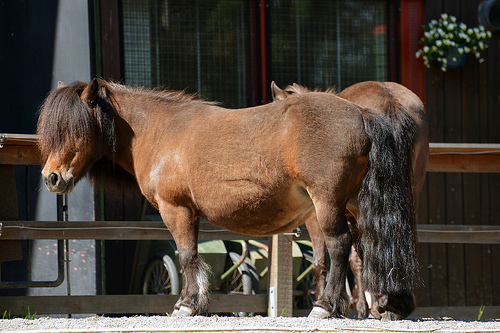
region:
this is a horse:
[22, 44, 448, 274]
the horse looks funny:
[29, 54, 487, 268]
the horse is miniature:
[49, 54, 409, 290]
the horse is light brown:
[100, 59, 370, 254]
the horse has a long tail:
[345, 119, 465, 274]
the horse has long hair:
[42, 84, 112, 144]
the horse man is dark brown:
[30, 64, 67, 108]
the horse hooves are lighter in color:
[302, 304, 350, 317]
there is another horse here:
[340, 64, 407, 110]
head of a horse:
[19, 47, 131, 204]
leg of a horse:
[154, 190, 227, 302]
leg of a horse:
[295, 188, 390, 308]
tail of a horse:
[358, 145, 423, 266]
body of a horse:
[134, 67, 382, 259]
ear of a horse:
[76, 78, 118, 115]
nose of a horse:
[30, 161, 65, 196]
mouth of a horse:
[33, 170, 85, 207]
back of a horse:
[160, 93, 294, 132]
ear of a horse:
[268, 75, 293, 101]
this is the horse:
[35, 71, 370, 318]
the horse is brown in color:
[39, 71, 364, 309]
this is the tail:
[364, 128, 399, 288]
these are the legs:
[162, 217, 206, 332]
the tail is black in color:
[359, 110, 399, 290]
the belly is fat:
[200, 145, 290, 232]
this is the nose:
[42, 167, 58, 191]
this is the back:
[199, 92, 280, 139]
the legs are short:
[159, 214, 217, 319]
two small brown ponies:
[18, 59, 475, 326]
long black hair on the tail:
[353, 116, 419, 291]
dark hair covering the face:
[27, 84, 103, 157]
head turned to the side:
[36, 75, 130, 193]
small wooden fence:
[1, 114, 498, 321]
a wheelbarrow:
[121, 195, 262, 305]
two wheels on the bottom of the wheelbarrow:
[133, 250, 267, 308]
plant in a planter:
[414, 5, 486, 76]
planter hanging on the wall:
[412, 10, 495, 77]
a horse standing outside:
[7, 28, 353, 332]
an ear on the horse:
[58, 62, 115, 120]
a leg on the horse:
[262, 181, 362, 331]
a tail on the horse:
[315, 119, 411, 284]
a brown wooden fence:
[392, 112, 494, 276]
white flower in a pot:
[461, 21, 482, 45]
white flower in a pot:
[422, 21, 462, 49]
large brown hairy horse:
[39, 80, 415, 317]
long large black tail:
[361, 114, 424, 293]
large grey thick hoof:
[170, 302, 197, 317]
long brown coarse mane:
[34, 81, 221, 157]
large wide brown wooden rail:
[0, 131, 499, 317]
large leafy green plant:
[413, 12, 499, 75]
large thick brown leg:
[304, 184, 354, 318]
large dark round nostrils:
[39, 169, 64, 190]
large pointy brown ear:
[81, 76, 103, 108]